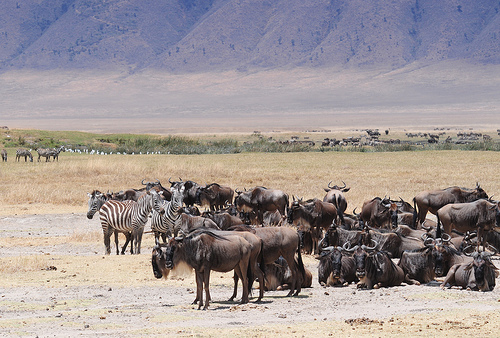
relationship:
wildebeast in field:
[437, 245, 499, 291] [0, 123, 498, 335]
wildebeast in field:
[195, 172, 245, 216] [0, 123, 498, 335]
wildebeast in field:
[313, 215, 375, 263] [0, 162, 486, 332]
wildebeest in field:
[162, 227, 260, 310] [0, 123, 498, 335]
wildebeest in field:
[345, 240, 410, 290] [0, 123, 498, 335]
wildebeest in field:
[322, 180, 348, 224] [0, 123, 498, 335]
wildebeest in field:
[395, 235, 444, 285] [0, 123, 498, 335]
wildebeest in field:
[313, 235, 409, 291] [0, 123, 498, 335]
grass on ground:
[1, 155, 497, 211] [4, 152, 498, 333]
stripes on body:
[136, 203, 161, 221] [97, 188, 165, 253]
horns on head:
[357, 234, 400, 257] [344, 248, 371, 284]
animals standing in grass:
[1, 136, 66, 169] [2, 148, 498, 209]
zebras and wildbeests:
[81, 175, 168, 256] [361, 181, 460, 288]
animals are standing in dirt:
[77, 168, 498, 300] [1, 197, 488, 329]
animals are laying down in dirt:
[77, 168, 498, 300] [1, 197, 488, 329]